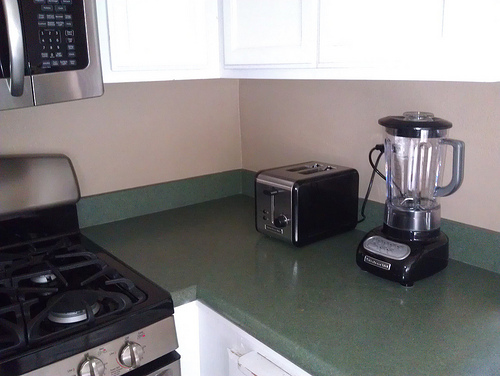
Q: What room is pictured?
A: It is a kitchen.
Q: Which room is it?
A: It is a kitchen.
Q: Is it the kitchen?
A: Yes, it is the kitchen.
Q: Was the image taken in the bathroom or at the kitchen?
A: It was taken at the kitchen.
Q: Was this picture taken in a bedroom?
A: No, the picture was taken in a kitchen.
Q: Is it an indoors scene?
A: Yes, it is indoors.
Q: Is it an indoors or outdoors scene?
A: It is indoors.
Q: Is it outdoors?
A: No, it is indoors.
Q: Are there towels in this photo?
A: No, there are no towels.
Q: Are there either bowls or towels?
A: No, there are no towels or bowls.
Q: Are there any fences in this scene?
A: No, there are no fences.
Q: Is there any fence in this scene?
A: No, there are no fences.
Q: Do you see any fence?
A: No, there are no fences.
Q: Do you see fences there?
A: No, there are no fences.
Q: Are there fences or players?
A: No, there are no fences or players.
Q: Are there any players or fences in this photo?
A: No, there are no fences or players.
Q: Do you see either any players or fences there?
A: No, there are no fences or players.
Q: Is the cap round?
A: Yes, the cap is round.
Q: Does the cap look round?
A: Yes, the cap is round.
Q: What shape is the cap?
A: The cap is round.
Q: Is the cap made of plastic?
A: Yes, the cap is made of plastic.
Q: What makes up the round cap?
A: The cap is made of plastic.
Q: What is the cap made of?
A: The cap is made of plastic.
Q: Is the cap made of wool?
A: No, the cap is made of plastic.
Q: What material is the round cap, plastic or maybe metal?
A: The cap is made of plastic.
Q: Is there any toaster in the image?
A: Yes, there is a toaster.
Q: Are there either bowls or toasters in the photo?
A: Yes, there is a toaster.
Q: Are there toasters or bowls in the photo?
A: Yes, there is a toaster.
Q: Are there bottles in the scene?
A: No, there are no bottles.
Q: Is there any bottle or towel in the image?
A: No, there are no bottles or towels.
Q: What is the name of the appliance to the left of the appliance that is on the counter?
A: The appliance is a toaster.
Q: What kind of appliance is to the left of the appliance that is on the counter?
A: The appliance is a toaster.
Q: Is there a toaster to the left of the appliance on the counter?
A: Yes, there is a toaster to the left of the appliance.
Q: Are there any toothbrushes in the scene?
A: No, there are no toothbrushes.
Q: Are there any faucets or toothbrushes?
A: No, there are no toothbrushes or faucets.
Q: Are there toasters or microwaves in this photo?
A: Yes, there is a toaster.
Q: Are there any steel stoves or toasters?
A: Yes, there is a steel toaster.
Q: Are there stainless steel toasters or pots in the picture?
A: Yes, there is a stainless steel toaster.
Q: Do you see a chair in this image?
A: No, there are no chairs.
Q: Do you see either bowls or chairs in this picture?
A: No, there are no chairs or bowls.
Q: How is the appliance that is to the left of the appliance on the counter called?
A: The appliance is a toaster.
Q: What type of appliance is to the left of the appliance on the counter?
A: The appliance is a toaster.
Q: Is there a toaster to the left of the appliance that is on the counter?
A: Yes, there is a toaster to the left of the appliance.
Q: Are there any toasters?
A: Yes, there is a toaster.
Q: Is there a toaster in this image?
A: Yes, there is a toaster.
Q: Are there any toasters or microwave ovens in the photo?
A: Yes, there is a toaster.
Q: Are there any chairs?
A: No, there are no chairs.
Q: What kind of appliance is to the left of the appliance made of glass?
A: The appliance is a toaster.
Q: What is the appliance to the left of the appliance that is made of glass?
A: The appliance is a toaster.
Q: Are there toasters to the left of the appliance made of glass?
A: Yes, there is a toaster to the left of the appliance.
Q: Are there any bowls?
A: No, there are no bowls.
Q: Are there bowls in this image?
A: No, there are no bowls.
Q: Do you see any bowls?
A: No, there are no bowls.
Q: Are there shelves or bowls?
A: No, there are no bowls or shelves.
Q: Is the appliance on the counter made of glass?
A: Yes, the appliance is made of glass.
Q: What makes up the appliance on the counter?
A: The appliance is made of glass.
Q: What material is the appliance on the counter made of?
A: The appliance is made of glass.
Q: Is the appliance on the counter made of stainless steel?
A: No, the appliance is made of glass.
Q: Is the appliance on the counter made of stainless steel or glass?
A: The appliance is made of glass.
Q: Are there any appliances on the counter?
A: Yes, there is an appliance on the counter.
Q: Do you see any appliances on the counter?
A: Yes, there is an appliance on the counter.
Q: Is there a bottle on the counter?
A: No, there is an appliance on the counter.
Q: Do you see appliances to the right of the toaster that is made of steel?
A: Yes, there is an appliance to the right of the toaster.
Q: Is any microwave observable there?
A: Yes, there is a microwave.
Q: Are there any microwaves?
A: Yes, there is a microwave.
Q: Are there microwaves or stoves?
A: Yes, there is a microwave.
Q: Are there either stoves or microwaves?
A: Yes, there is a microwave.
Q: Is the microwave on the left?
A: Yes, the microwave is on the left of the image.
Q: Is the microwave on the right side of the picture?
A: No, the microwave is on the left of the image.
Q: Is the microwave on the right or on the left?
A: The microwave is on the left of the image.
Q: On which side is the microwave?
A: The microwave is on the left of the image.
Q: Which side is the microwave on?
A: The microwave is on the left of the image.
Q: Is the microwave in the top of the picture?
A: Yes, the microwave is in the top of the image.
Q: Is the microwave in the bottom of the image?
A: No, the microwave is in the top of the image.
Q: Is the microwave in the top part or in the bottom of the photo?
A: The microwave is in the top of the image.